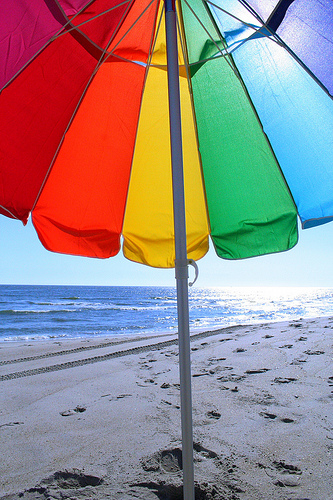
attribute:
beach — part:
[23, 311, 332, 491]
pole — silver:
[155, 71, 226, 367]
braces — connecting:
[36, 0, 291, 59]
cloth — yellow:
[117, 0, 212, 271]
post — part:
[152, 12, 217, 479]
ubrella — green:
[1, 0, 332, 268]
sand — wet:
[248, 376, 307, 439]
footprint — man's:
[273, 375, 297, 384]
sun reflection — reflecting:
[235, 286, 295, 320]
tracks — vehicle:
[56, 328, 147, 370]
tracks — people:
[196, 304, 274, 477]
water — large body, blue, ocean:
[0, 282, 330, 343]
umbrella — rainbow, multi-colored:
[0, 7, 332, 272]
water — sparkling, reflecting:
[3, 278, 330, 339]